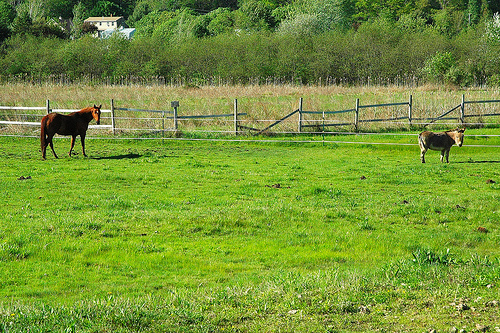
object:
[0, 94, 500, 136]
fence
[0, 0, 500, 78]
trees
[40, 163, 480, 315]
lawn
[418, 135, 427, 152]
tail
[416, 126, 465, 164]
donkey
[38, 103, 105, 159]
book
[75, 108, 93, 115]
mane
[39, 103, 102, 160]
horse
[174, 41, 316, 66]
leaves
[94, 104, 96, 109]
ear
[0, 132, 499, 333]
green pasture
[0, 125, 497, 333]
grass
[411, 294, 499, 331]
rocks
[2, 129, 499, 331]
pasture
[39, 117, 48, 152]
tail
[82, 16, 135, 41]
house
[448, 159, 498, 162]
shadow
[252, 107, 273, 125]
part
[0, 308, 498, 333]
edge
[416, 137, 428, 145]
part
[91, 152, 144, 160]
shadow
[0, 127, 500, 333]
field